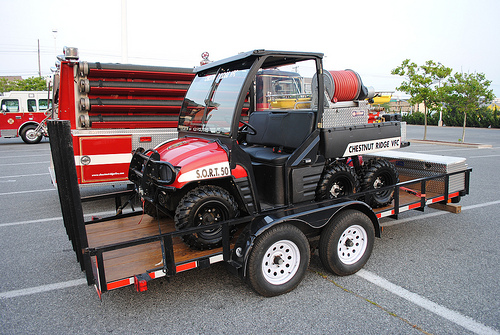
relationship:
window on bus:
[0, 92, 37, 126] [4, 86, 53, 144]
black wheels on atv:
[174, 186, 236, 248] [128, 49, 408, 249]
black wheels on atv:
[316, 163, 360, 203] [128, 49, 408, 249]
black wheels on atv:
[367, 155, 397, 205] [128, 49, 408, 249]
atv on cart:
[128, 49, 408, 249] [38, 119, 470, 301]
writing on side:
[192, 146, 226, 182] [325, 120, 405, 158]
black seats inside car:
[241, 110, 313, 162] [129, 47, 406, 245]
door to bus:
[0, 98, 19, 136] [0, 91, 53, 145]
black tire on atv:
[248, 224, 310, 298] [133, 40, 375, 212]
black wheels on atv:
[174, 186, 240, 250] [126, 49, 412, 249]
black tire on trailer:
[248, 224, 310, 298] [45, 66, 442, 303]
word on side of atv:
[348, 140, 374, 154] [128, 49, 408, 249]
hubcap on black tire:
[261, 238, 300, 284] [248, 224, 310, 298]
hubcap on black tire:
[338, 222, 368, 263] [319, 210, 375, 277]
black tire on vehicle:
[324, 205, 380, 275] [79, 207, 190, 281]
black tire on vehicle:
[242, 228, 309, 293] [79, 207, 190, 281]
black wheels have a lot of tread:
[356, 158, 399, 208] [359, 157, 383, 184]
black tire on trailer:
[248, 224, 310, 298] [47, 90, 471, 309]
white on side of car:
[180, 156, 240, 188] [129, 47, 406, 245]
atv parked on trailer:
[139, 56, 420, 230] [41, 157, 492, 295]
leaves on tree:
[404, 74, 483, 92] [387, 55, 453, 138]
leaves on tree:
[404, 74, 483, 92] [429, 64, 497, 145]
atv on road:
[128, 49, 408, 249] [0, 123, 499, 333]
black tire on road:
[248, 224, 310, 298] [146, 233, 484, 327]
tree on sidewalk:
[390, 60, 455, 140] [397, 125, 493, 139]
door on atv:
[232, 53, 328, 218] [128, 49, 408, 249]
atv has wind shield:
[128, 49, 408, 249] [132, 52, 413, 242]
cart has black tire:
[45, 47, 471, 301] [248, 224, 310, 298]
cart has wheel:
[45, 47, 471, 301] [314, 202, 385, 277]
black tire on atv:
[248, 224, 310, 298] [119, 42, 400, 252]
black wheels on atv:
[316, 165, 361, 201] [135, 40, 420, 243]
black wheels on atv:
[356, 158, 399, 208] [135, 40, 420, 243]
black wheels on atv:
[356, 158, 399, 208] [123, 37, 455, 239]